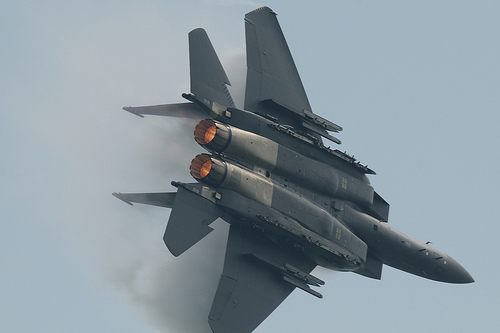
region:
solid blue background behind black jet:
[27, 22, 478, 318]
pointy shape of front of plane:
[372, 220, 472, 285]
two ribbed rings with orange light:
[180, 115, 230, 185]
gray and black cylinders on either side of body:
[215, 121, 371, 261]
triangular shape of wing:
[202, 5, 327, 330]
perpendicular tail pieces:
[140, 25, 230, 120]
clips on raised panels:
[255, 246, 330, 296]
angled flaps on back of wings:
[235, 15, 262, 110]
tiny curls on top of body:
[415, 240, 442, 265]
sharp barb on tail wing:
[215, 65, 235, 95]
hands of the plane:
[168, 8, 318, 78]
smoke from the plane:
[131, 254, 218, 331]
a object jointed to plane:
[226, 232, 354, 306]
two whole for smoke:
[188, 117, 225, 187]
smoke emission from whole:
[176, 109, 239, 204]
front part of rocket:
[389, 200, 498, 313]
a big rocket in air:
[72, 26, 485, 315]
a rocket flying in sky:
[50, 10, 474, 310]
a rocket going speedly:
[60, 3, 495, 307]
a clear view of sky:
[46, 8, 492, 156]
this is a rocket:
[137, 71, 491, 318]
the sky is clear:
[361, 88, 469, 176]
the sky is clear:
[108, 118, 182, 199]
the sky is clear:
[94, 245, 139, 300]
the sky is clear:
[341, 66, 411, 126]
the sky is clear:
[50, 81, 121, 156]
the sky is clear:
[34, 93, 109, 173]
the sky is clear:
[52, 115, 94, 215]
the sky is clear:
[340, 279, 437, 330]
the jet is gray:
[105, 11, 498, 296]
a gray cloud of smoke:
[108, 125, 227, 330]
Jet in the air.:
[142, 22, 459, 320]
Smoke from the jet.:
[79, 82, 290, 317]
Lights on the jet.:
[147, 92, 262, 214]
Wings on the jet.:
[168, 23, 388, 325]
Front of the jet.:
[337, 177, 482, 319]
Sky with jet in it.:
[21, 78, 285, 315]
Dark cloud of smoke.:
[150, 85, 315, 327]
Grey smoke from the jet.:
[109, 61, 271, 325]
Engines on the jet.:
[158, 53, 445, 328]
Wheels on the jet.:
[380, 205, 490, 304]